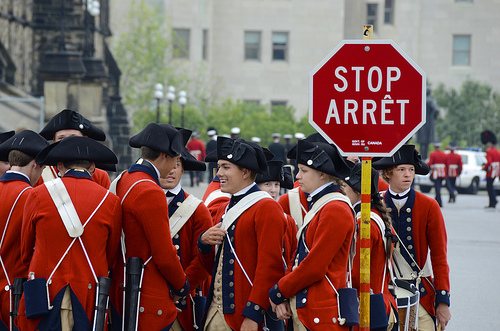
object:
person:
[193, 128, 292, 330]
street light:
[153, 83, 163, 102]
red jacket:
[384, 190, 451, 315]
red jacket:
[270, 187, 356, 329]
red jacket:
[198, 182, 285, 328]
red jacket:
[105, 167, 185, 329]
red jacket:
[18, 171, 122, 329]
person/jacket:
[117, 121, 189, 328]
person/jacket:
[21, 137, 120, 329]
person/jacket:
[427, 142, 446, 207]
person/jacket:
[482, 128, 499, 209]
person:
[19, 130, 109, 328]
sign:
[308, 41, 425, 157]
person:
[270, 143, 356, 328]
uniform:
[118, 169, 184, 329]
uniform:
[199, 187, 285, 328]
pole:
[351, 22, 381, 329]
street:
[180, 181, 498, 329]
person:
[378, 144, 450, 329]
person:
[425, 142, 447, 207]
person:
[445, 144, 462, 203]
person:
[108, 122, 186, 329]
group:
[0, 106, 456, 329]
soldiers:
[1, 105, 450, 330]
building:
[1, 0, 133, 179]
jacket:
[14, 172, 119, 321]